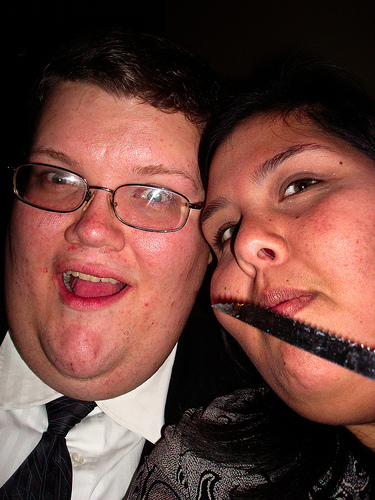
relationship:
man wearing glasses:
[19, 64, 206, 405] [7, 156, 198, 231]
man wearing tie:
[19, 64, 206, 405] [11, 396, 95, 499]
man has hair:
[19, 64, 206, 405] [42, 30, 222, 106]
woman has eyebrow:
[203, 94, 374, 417] [239, 141, 342, 181]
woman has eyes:
[203, 94, 374, 417] [216, 176, 330, 255]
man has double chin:
[19, 64, 206, 405] [3, 311, 180, 404]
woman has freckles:
[203, 94, 374, 417] [310, 225, 374, 273]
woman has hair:
[203, 94, 374, 417] [194, 69, 372, 145]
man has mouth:
[19, 64, 206, 405] [52, 253, 136, 321]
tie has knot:
[11, 396, 95, 499] [43, 399, 89, 437]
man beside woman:
[19, 64, 206, 405] [203, 94, 374, 417]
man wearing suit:
[19, 64, 206, 405] [3, 340, 219, 498]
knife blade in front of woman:
[208, 298, 374, 393] [203, 94, 374, 417]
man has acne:
[19, 64, 206, 405] [65, 243, 84, 255]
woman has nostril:
[203, 94, 374, 417] [252, 246, 276, 264]